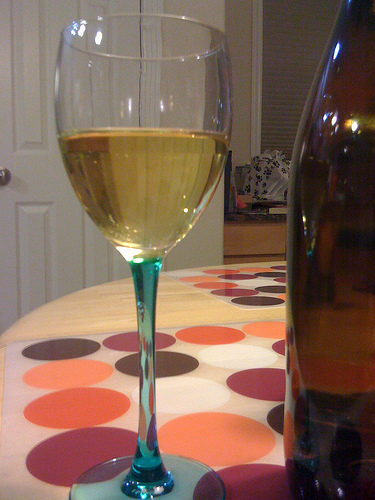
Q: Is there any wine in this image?
A: Yes, there is wine.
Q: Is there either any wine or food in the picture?
A: Yes, there is wine.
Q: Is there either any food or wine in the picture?
A: Yes, there is wine.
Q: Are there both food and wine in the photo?
A: No, there is wine but no food.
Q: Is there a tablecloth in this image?
A: No, there are no tablecloths.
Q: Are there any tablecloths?
A: No, there are no tablecloths.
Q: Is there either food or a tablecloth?
A: No, there are no tablecloths or food.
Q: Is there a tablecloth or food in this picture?
A: No, there are no tablecloths or food.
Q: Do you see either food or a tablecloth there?
A: No, there are no tablecloths or food.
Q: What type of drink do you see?
A: The drink is wine.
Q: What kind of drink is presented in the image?
A: The drink is wine.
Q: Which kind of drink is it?
A: The drink is wine.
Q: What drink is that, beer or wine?
A: This is wine.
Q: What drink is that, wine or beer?
A: This is wine.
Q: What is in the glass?
A: The wine is in the glass.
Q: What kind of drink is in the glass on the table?
A: The drink is wine.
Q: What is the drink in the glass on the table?
A: The drink is wine.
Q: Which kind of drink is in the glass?
A: The drink is wine.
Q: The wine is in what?
A: The wine is in the glass.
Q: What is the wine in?
A: The wine is in the glass.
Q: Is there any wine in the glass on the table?
A: Yes, there is wine in the glass.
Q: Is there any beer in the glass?
A: No, there is wine in the glass.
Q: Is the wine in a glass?
A: Yes, the wine is in a glass.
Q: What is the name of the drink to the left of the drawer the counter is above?
A: The drink is wine.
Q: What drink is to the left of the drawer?
A: The drink is wine.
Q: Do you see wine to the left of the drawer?
A: Yes, there is wine to the left of the drawer.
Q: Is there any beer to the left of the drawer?
A: No, there is wine to the left of the drawer.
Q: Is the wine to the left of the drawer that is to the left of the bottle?
A: Yes, the wine is to the left of the drawer.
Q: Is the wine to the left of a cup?
A: No, the wine is to the left of the drawer.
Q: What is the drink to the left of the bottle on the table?
A: The drink is wine.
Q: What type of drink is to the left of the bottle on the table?
A: The drink is wine.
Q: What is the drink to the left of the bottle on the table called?
A: The drink is wine.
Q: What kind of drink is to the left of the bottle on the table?
A: The drink is wine.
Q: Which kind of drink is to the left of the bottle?
A: The drink is wine.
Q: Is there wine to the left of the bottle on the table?
A: Yes, there is wine to the left of the bottle.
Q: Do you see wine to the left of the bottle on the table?
A: Yes, there is wine to the left of the bottle.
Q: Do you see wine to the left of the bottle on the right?
A: Yes, there is wine to the left of the bottle.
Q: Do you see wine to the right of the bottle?
A: No, the wine is to the left of the bottle.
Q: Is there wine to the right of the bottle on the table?
A: No, the wine is to the left of the bottle.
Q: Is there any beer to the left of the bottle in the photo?
A: No, there is wine to the left of the bottle.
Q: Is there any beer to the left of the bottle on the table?
A: No, there is wine to the left of the bottle.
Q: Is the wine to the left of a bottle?
A: Yes, the wine is to the left of a bottle.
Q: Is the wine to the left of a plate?
A: No, the wine is to the left of a bottle.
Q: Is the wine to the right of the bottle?
A: No, the wine is to the left of the bottle.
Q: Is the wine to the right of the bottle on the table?
A: No, the wine is to the left of the bottle.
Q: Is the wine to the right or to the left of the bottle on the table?
A: The wine is to the left of the bottle.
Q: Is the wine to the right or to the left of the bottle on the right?
A: The wine is to the left of the bottle.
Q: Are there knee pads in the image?
A: No, there are no knee pads.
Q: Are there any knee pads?
A: No, there are no knee pads.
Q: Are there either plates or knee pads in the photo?
A: No, there are no knee pads or plates.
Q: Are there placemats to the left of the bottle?
A: Yes, there is a placemat to the left of the bottle.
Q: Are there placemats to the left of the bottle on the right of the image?
A: Yes, there is a placemat to the left of the bottle.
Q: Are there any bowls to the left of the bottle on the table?
A: No, there is a placemat to the left of the bottle.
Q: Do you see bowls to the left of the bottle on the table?
A: No, there is a placemat to the left of the bottle.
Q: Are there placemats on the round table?
A: Yes, there is a placemat on the table.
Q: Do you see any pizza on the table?
A: No, there is a placemat on the table.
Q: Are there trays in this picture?
A: No, there are no trays.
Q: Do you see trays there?
A: No, there are no trays.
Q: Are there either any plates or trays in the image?
A: No, there are no trays or plates.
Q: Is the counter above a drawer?
A: Yes, the counter is above a drawer.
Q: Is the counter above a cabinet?
A: No, the counter is above a drawer.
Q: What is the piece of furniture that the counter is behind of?
A: The piece of furniture is a table.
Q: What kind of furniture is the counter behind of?
A: The counter is behind the table.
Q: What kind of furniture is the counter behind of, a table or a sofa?
A: The counter is behind a table.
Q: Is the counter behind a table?
A: Yes, the counter is behind a table.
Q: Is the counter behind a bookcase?
A: No, the counter is behind a table.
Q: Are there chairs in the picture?
A: No, there are no chairs.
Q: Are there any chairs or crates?
A: No, there are no chairs or crates.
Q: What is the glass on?
A: The glass is on the table.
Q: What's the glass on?
A: The glass is on the table.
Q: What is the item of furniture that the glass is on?
A: The piece of furniture is a table.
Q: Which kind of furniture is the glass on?
A: The glass is on the table.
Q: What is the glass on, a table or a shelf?
A: The glass is on a table.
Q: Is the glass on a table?
A: Yes, the glass is on a table.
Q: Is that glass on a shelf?
A: No, the glass is on a table.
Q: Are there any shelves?
A: No, there are no shelves.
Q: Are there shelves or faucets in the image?
A: No, there are no shelves or faucets.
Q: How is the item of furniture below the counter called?
A: The piece of furniture is a drawer.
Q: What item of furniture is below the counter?
A: The piece of furniture is a drawer.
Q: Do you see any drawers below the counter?
A: Yes, there is a drawer below the counter.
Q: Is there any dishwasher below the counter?
A: No, there is a drawer below the counter.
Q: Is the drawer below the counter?
A: Yes, the drawer is below the counter.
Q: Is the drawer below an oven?
A: No, the drawer is below the counter.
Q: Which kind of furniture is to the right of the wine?
A: The piece of furniture is a drawer.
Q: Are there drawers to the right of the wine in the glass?
A: Yes, there is a drawer to the right of the wine.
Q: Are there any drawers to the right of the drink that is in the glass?
A: Yes, there is a drawer to the right of the wine.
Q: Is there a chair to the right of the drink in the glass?
A: No, there is a drawer to the right of the wine.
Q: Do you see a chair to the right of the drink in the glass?
A: No, there is a drawer to the right of the wine.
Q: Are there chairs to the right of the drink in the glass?
A: No, there is a drawer to the right of the wine.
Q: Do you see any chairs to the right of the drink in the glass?
A: No, there is a drawer to the right of the wine.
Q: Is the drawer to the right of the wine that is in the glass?
A: Yes, the drawer is to the right of the wine.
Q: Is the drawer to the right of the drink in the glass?
A: Yes, the drawer is to the right of the wine.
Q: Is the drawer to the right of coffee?
A: No, the drawer is to the right of the wine.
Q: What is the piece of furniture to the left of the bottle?
A: The piece of furniture is a drawer.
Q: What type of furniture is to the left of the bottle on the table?
A: The piece of furniture is a drawer.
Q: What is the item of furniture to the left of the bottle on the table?
A: The piece of furniture is a drawer.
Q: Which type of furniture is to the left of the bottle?
A: The piece of furniture is a drawer.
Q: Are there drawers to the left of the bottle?
A: Yes, there is a drawer to the left of the bottle.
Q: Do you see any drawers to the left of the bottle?
A: Yes, there is a drawer to the left of the bottle.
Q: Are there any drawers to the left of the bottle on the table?
A: Yes, there is a drawer to the left of the bottle.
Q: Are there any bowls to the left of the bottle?
A: No, there is a drawer to the left of the bottle.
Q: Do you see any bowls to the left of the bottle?
A: No, there is a drawer to the left of the bottle.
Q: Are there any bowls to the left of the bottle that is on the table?
A: No, there is a drawer to the left of the bottle.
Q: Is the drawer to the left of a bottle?
A: Yes, the drawer is to the left of a bottle.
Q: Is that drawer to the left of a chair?
A: No, the drawer is to the left of a bottle.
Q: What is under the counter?
A: The drawer is under the counter.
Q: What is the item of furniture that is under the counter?
A: The piece of furniture is a drawer.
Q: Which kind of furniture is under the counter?
A: The piece of furniture is a drawer.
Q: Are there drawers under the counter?
A: Yes, there is a drawer under the counter.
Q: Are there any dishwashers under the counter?
A: No, there is a drawer under the counter.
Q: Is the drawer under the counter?
A: Yes, the drawer is under the counter.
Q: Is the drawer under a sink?
A: No, the drawer is under the counter.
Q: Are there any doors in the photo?
A: Yes, there is a door.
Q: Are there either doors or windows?
A: Yes, there is a door.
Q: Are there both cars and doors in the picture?
A: No, there is a door but no cars.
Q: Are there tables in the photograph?
A: Yes, there is a table.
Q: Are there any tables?
A: Yes, there is a table.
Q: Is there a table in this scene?
A: Yes, there is a table.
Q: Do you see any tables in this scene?
A: Yes, there is a table.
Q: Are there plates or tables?
A: Yes, there is a table.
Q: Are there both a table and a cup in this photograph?
A: No, there is a table but no cups.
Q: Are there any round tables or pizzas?
A: Yes, there is a round table.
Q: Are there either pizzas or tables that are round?
A: Yes, the table is round.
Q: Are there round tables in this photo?
A: Yes, there is a round table.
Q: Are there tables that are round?
A: Yes, there is a table that is round.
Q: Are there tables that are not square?
A: Yes, there is a round table.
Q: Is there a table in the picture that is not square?
A: Yes, there is a round table.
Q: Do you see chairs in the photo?
A: No, there are no chairs.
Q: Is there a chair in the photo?
A: No, there are no chairs.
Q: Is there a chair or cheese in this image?
A: No, there are no chairs or cheese.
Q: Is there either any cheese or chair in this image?
A: No, there are no chairs or cheese.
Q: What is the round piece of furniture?
A: The piece of furniture is a table.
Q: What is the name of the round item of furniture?
A: The piece of furniture is a table.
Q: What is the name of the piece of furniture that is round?
A: The piece of furniture is a table.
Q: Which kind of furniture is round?
A: The furniture is a table.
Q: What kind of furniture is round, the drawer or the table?
A: The table is round.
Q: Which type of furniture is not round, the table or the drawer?
A: The drawer is not round.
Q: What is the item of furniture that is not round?
A: The piece of furniture is a drawer.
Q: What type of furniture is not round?
A: The furniture is a drawer.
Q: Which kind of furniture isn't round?
A: The furniture is a drawer.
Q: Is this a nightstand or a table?
A: This is a table.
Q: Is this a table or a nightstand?
A: This is a table.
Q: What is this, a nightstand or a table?
A: This is a table.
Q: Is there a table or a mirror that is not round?
A: No, there is a table but it is round.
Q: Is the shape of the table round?
A: Yes, the table is round.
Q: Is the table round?
A: Yes, the table is round.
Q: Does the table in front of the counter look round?
A: Yes, the table is round.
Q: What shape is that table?
A: The table is round.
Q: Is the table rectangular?
A: No, the table is round.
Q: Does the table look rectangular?
A: No, the table is round.